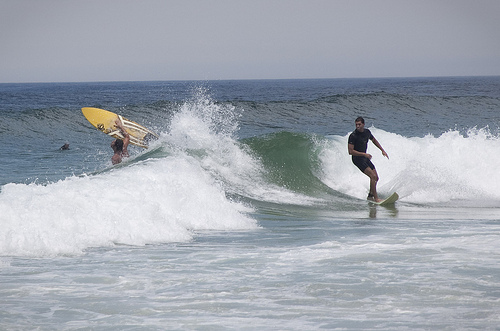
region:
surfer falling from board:
[69, 95, 176, 158]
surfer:
[336, 105, 390, 199]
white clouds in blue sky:
[22, 32, 63, 60]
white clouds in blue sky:
[157, 21, 196, 59]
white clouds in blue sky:
[384, 20, 414, 47]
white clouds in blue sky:
[315, 20, 347, 47]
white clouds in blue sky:
[234, 28, 271, 58]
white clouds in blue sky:
[170, 15, 225, 72]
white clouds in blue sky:
[129, 0, 194, 59]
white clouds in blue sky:
[73, 26, 111, 66]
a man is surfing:
[348, 114, 400, 207]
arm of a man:
[346, 141, 374, 158]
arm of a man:
[370, 134, 390, 158]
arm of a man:
[113, 120, 130, 152]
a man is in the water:
[109, 117, 132, 169]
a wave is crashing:
[1, 96, 273, 258]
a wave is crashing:
[327, 124, 497, 209]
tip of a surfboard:
[381, 191, 398, 206]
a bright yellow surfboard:
[77, 102, 159, 150]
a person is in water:
[57, 141, 72, 152]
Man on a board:
[359, 190, 404, 210]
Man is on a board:
[354, 184, 403, 210]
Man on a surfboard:
[355, 180, 405, 210]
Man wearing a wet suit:
[345, 125, 375, 170]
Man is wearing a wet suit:
[342, 125, 374, 170]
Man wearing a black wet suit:
[347, 127, 386, 173]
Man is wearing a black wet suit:
[342, 127, 379, 173]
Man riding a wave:
[342, 111, 408, 211]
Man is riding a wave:
[346, 113, 403, 210]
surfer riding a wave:
[346, 117, 401, 204]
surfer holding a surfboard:
[78, 105, 158, 165]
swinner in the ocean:
[54, 142, 73, 152]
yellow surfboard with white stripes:
[79, 106, 161, 147]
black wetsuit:
[346, 126, 375, 168]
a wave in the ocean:
[0, 87, 497, 147]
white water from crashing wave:
[0, 82, 498, 260]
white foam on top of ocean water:
[0, 217, 497, 329]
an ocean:
[0, 75, 497, 330]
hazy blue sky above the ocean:
[0, 1, 499, 84]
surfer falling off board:
[69, 96, 145, 177]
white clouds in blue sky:
[20, 18, 41, 40]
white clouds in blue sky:
[124, 28, 164, 64]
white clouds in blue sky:
[405, 18, 445, 48]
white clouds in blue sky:
[322, 2, 370, 68]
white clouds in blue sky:
[212, 2, 249, 40]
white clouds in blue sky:
[257, 11, 295, 56]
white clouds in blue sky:
[112, 19, 184, 72]